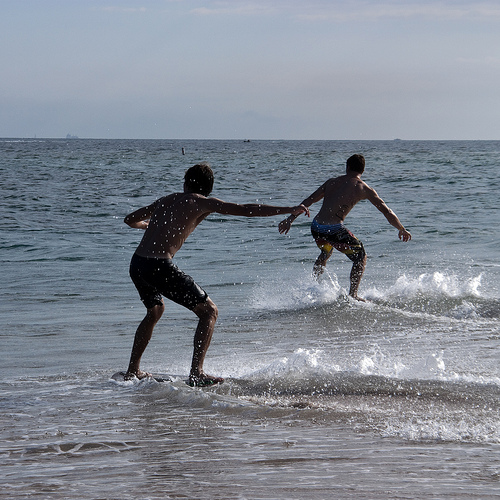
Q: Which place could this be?
A: It is an ocean.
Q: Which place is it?
A: It is an ocean.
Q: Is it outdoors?
A: Yes, it is outdoors.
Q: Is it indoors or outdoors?
A: It is outdoors.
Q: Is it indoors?
A: No, it is outdoors.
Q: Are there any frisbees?
A: No, there are no frisbees.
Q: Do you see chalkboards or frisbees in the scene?
A: No, there are no frisbees or chalkboards.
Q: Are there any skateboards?
A: No, there are no skateboards.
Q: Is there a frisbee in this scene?
A: No, there are no frisbees.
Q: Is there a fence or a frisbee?
A: No, there are no frisbees or fences.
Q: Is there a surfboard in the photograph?
A: Yes, there is a surfboard.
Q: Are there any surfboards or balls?
A: Yes, there is a surfboard.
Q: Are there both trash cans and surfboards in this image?
A: No, there is a surfboard but no trash cans.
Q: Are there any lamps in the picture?
A: No, there are no lamps.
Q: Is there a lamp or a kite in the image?
A: No, there are no lamps or kites.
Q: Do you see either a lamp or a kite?
A: No, there are no lamps or kites.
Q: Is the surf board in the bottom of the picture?
A: Yes, the surf board is in the bottom of the image.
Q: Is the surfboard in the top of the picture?
A: No, the surfboard is in the bottom of the image.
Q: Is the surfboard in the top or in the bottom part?
A: The surfboard is in the bottom of the image.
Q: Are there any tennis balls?
A: No, there are no tennis balls.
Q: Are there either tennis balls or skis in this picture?
A: No, there are no tennis balls or skis.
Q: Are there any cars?
A: No, there are no cars.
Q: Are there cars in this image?
A: No, there are no cars.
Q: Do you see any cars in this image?
A: No, there are no cars.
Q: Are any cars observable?
A: No, there are no cars.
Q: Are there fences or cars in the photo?
A: No, there are no cars or fences.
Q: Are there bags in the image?
A: No, there are no bags.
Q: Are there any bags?
A: No, there are no bags.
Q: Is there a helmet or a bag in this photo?
A: No, there are no bags or helmets.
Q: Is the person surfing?
A: Yes, the person is surfing.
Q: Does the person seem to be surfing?
A: Yes, the person is surfing.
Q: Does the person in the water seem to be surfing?
A: Yes, the person is surfing.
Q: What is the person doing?
A: The person is surfing.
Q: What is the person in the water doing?
A: The person is surfing.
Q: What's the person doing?
A: The person is surfing.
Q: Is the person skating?
A: No, the person is surfing.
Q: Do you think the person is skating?
A: No, the person is surfing.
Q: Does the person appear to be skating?
A: No, the person is surfing.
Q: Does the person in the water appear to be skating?
A: No, the person is surfing.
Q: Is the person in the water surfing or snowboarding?
A: The person is surfing.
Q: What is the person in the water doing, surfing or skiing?
A: The person is surfing.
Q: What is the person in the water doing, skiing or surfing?
A: The person is surfing.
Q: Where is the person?
A: The person is in the water.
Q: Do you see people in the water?
A: Yes, there is a person in the water.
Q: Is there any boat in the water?
A: No, there is a person in the water.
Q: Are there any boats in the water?
A: No, there is a person in the water.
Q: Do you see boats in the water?
A: No, there is a person in the water.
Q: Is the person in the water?
A: Yes, the person is in the water.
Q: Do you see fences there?
A: No, there are no fences.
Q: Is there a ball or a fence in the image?
A: No, there are no fences or balls.